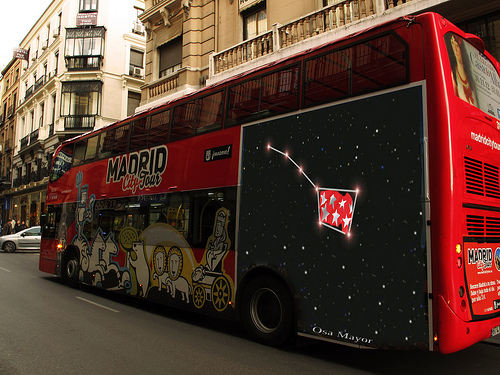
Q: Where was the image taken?
A: It was taken at the street.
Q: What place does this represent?
A: It represents the street.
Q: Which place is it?
A: It is a street.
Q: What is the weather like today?
A: It is overcast.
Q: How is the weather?
A: It is overcast.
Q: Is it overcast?
A: Yes, it is overcast.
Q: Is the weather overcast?
A: Yes, it is overcast.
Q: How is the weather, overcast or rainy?
A: It is overcast.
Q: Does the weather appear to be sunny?
A: No, it is overcast.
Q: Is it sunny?
A: No, it is overcast.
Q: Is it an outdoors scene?
A: Yes, it is outdoors.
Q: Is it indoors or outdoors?
A: It is outdoors.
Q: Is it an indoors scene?
A: No, it is outdoors.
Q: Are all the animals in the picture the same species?
A: Yes, all the animals are lions.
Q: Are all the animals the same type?
A: Yes, all the animals are lions.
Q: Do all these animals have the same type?
A: Yes, all the animals are lions.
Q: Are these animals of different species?
A: No, all the animals are lions.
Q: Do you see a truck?
A: No, there are no trucks.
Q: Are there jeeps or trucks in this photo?
A: No, there are no trucks or jeeps.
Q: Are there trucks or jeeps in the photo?
A: No, there are no trucks or jeeps.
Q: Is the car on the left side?
A: Yes, the car is on the left of the image.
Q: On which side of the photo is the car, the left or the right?
A: The car is on the left of the image.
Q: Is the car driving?
A: Yes, the car is driving.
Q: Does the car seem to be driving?
A: Yes, the car is driving.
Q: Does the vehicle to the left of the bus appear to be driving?
A: Yes, the car is driving.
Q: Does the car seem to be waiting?
A: No, the car is driving.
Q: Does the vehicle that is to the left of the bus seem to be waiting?
A: No, the car is driving.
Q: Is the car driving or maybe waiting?
A: The car is driving.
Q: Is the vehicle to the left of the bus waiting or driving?
A: The car is driving.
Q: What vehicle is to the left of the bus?
A: The vehicle is a car.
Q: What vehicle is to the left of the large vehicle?
A: The vehicle is a car.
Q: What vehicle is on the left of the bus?
A: The vehicle is a car.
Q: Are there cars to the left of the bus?
A: Yes, there is a car to the left of the bus.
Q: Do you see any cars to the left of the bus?
A: Yes, there is a car to the left of the bus.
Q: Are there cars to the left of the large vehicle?
A: Yes, there is a car to the left of the bus.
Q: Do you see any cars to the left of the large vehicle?
A: Yes, there is a car to the left of the bus.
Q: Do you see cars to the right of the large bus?
A: No, the car is to the left of the bus.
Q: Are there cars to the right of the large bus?
A: No, the car is to the left of the bus.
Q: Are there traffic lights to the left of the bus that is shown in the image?
A: No, there is a car to the left of the bus.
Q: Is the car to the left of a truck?
A: No, the car is to the left of a bus.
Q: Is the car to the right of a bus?
A: No, the car is to the left of a bus.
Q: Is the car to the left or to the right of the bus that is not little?
A: The car is to the left of the bus.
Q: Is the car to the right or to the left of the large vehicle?
A: The car is to the left of the bus.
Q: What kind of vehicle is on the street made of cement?
A: The vehicle is a car.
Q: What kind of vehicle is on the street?
A: The vehicle is a car.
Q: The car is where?
A: The car is on the street.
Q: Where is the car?
A: The car is on the street.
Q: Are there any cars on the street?
A: Yes, there is a car on the street.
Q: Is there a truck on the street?
A: No, there is a car on the street.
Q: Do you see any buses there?
A: Yes, there is a bus.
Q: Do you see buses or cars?
A: Yes, there is a bus.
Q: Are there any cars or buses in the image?
A: Yes, there is a bus.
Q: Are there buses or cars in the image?
A: Yes, there is a bus.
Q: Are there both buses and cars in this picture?
A: Yes, there are both a bus and a car.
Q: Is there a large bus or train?
A: Yes, there is a large bus.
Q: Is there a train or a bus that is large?
A: Yes, the bus is large.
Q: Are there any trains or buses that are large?
A: Yes, the bus is large.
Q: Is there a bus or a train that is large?
A: Yes, the bus is large.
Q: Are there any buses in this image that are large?
A: Yes, there is a large bus.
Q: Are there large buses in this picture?
A: Yes, there is a large bus.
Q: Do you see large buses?
A: Yes, there is a large bus.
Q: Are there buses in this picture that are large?
A: Yes, there is a large bus.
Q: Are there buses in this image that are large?
A: Yes, there is a bus that is large.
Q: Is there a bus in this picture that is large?
A: Yes, there is a bus that is large.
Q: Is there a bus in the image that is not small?
A: Yes, there is a large bus.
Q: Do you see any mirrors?
A: No, there are no mirrors.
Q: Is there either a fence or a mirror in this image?
A: No, there are no mirrors or fences.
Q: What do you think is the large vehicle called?
A: The vehicle is a bus.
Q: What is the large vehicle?
A: The vehicle is a bus.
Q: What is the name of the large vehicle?
A: The vehicle is a bus.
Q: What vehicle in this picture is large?
A: The vehicle is a bus.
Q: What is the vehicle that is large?
A: The vehicle is a bus.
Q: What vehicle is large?
A: The vehicle is a bus.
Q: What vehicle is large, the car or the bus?
A: The bus is large.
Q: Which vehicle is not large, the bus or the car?
A: The car is not large.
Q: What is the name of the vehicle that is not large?
A: The vehicle is a car.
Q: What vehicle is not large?
A: The vehicle is a car.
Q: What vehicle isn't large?
A: The vehicle is a car.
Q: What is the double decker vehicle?
A: The vehicle is a bus.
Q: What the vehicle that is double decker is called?
A: The vehicle is a bus.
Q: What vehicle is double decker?
A: The vehicle is a bus.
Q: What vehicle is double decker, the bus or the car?
A: The bus is double decker.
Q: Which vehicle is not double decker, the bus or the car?
A: The car is not double decker.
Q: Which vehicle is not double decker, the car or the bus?
A: The car is not double decker.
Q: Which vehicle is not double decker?
A: The vehicle is a car.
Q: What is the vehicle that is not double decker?
A: The vehicle is a car.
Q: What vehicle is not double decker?
A: The vehicle is a car.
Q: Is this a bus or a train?
A: This is a bus.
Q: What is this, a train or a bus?
A: This is a bus.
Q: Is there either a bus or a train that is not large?
A: No, there is a bus but it is large.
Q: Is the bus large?
A: Yes, the bus is large.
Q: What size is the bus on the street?
A: The bus is large.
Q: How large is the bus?
A: The bus is large.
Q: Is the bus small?
A: No, the bus is large.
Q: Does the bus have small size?
A: No, the bus is large.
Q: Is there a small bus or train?
A: No, there is a bus but it is large.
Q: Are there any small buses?
A: No, there is a bus but it is large.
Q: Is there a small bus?
A: No, there is a bus but it is large.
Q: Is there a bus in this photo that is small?
A: No, there is a bus but it is large.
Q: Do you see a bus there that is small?
A: No, there is a bus but it is large.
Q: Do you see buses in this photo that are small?
A: No, there is a bus but it is large.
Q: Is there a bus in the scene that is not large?
A: No, there is a bus but it is large.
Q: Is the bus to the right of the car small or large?
A: The bus is large.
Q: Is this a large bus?
A: Yes, this is a large bus.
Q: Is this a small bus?
A: No, this is a large bus.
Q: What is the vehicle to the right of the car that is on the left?
A: The vehicle is a bus.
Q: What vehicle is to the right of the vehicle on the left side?
A: The vehicle is a bus.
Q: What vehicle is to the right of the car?
A: The vehicle is a bus.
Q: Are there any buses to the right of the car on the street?
A: Yes, there is a bus to the right of the car.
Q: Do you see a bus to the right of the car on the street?
A: Yes, there is a bus to the right of the car.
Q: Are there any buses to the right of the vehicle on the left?
A: Yes, there is a bus to the right of the car.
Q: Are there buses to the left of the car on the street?
A: No, the bus is to the right of the car.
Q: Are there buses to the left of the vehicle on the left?
A: No, the bus is to the right of the car.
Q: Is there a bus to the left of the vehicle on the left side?
A: No, the bus is to the right of the car.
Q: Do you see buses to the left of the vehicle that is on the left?
A: No, the bus is to the right of the car.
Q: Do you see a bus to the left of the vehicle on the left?
A: No, the bus is to the right of the car.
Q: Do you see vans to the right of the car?
A: No, there is a bus to the right of the car.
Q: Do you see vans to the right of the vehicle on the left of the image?
A: No, there is a bus to the right of the car.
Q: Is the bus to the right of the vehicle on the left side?
A: Yes, the bus is to the right of the car.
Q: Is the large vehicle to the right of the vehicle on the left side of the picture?
A: Yes, the bus is to the right of the car.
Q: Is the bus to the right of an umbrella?
A: No, the bus is to the right of the car.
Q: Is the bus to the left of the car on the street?
A: No, the bus is to the right of the car.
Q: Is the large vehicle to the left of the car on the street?
A: No, the bus is to the right of the car.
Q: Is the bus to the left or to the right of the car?
A: The bus is to the right of the car.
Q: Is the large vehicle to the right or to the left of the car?
A: The bus is to the right of the car.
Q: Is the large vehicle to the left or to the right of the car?
A: The bus is to the right of the car.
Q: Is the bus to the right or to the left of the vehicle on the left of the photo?
A: The bus is to the right of the car.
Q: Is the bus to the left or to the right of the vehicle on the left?
A: The bus is to the right of the car.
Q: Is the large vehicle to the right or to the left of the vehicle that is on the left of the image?
A: The bus is to the right of the car.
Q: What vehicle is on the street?
A: The vehicle is a bus.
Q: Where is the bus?
A: The bus is on the street.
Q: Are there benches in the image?
A: No, there are no benches.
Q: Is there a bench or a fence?
A: No, there are no benches or fences.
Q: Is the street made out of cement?
A: Yes, the street is made of cement.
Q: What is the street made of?
A: The street is made of concrete.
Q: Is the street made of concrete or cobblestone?
A: The street is made of concrete.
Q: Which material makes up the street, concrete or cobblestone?
A: The street is made of concrete.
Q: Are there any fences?
A: No, there are no fences.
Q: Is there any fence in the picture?
A: No, there are no fences.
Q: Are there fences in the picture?
A: No, there are no fences.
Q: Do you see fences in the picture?
A: No, there are no fences.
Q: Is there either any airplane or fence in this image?
A: No, there are no fences or airplanes.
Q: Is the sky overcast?
A: Yes, the sky is overcast.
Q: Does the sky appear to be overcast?
A: Yes, the sky is overcast.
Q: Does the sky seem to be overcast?
A: Yes, the sky is overcast.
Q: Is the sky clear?
A: No, the sky is overcast.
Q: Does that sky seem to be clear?
A: No, the sky is overcast.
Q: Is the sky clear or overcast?
A: The sky is overcast.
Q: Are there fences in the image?
A: No, there are no fences.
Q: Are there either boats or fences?
A: No, there are no fences or boats.